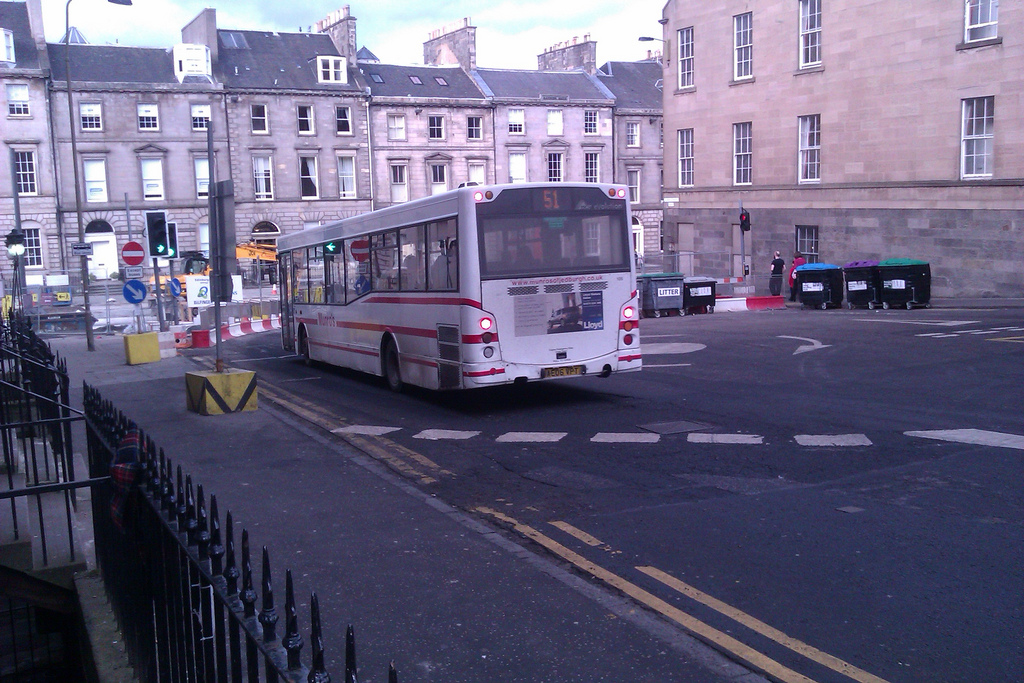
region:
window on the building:
[133, 148, 168, 206]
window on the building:
[296, 158, 332, 200]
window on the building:
[399, 157, 413, 199]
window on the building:
[516, 149, 537, 189]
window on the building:
[667, 132, 699, 180]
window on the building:
[725, 120, 764, 197]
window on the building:
[794, 135, 818, 190]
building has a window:
[83, 157, 107, 200]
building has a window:
[193, 154, 214, 202]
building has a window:
[251, 150, 271, 195]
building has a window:
[295, 150, 315, 198]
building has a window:
[332, 154, 353, 202]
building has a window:
[390, 158, 407, 200]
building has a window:
[330, 106, 351, 135]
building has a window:
[247, 100, 268, 132]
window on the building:
[939, 142, 982, 169]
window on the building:
[668, 29, 692, 94]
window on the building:
[725, 13, 758, 68]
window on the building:
[80, 145, 113, 206]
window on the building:
[431, 104, 489, 133]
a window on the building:
[295, 156, 315, 176]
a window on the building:
[787, 110, 836, 197]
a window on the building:
[725, 86, 765, 200]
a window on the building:
[664, 113, 713, 209]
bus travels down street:
[277, 177, 650, 408]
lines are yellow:
[260, 379, 878, 680]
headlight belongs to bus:
[479, 313, 493, 367]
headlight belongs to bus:
[623, 302, 639, 356]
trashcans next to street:
[791, 250, 937, 312]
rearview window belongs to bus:
[482, 215, 632, 276]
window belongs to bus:
[428, 212, 457, 290]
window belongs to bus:
[374, 232, 401, 291]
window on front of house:
[7, 80, 31, 119]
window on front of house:
[72, 98, 110, 137]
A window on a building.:
[797, 115, 826, 177]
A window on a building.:
[969, 13, 1001, 42]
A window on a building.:
[672, 133, 701, 190]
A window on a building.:
[680, 29, 696, 88]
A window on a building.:
[730, 13, 753, 78]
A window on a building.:
[585, 147, 599, 173]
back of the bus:
[359, 143, 746, 431]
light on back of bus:
[442, 287, 542, 360]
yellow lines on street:
[468, 492, 655, 603]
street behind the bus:
[565, 375, 844, 531]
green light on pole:
[128, 192, 195, 291]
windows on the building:
[626, 89, 880, 235]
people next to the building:
[748, 228, 848, 315]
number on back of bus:
[512, 168, 590, 239]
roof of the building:
[340, 37, 525, 127]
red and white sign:
[103, 220, 165, 291]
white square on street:
[324, 410, 405, 449]